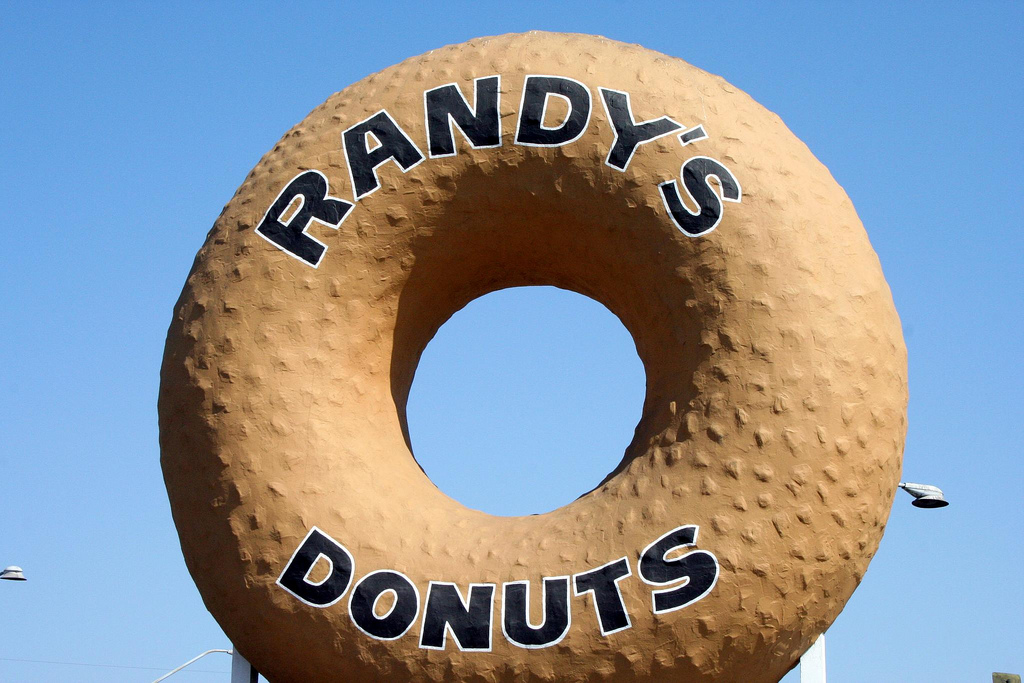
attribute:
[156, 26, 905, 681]
donut — brown, large, giant, sign, really large, blue, very large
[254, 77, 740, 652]
randy's donuts — black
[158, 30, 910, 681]
sign — brown, huge, three dimensional, bumpy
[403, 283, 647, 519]
sky — blue, clear, light blue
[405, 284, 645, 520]
donut hole — giant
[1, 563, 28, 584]
street light — white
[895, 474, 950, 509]
street light — nearby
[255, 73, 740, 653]
letters — black, white, curved, evenly spaced